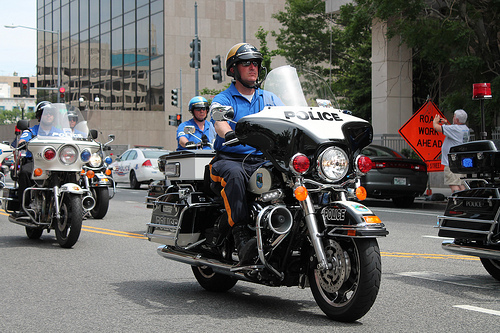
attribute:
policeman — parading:
[175, 95, 215, 150]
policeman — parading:
[15, 98, 64, 209]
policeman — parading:
[207, 40, 290, 255]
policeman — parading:
[67, 109, 77, 130]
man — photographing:
[431, 106, 472, 193]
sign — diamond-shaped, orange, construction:
[397, 95, 449, 169]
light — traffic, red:
[19, 76, 33, 97]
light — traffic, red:
[56, 84, 68, 102]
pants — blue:
[209, 155, 262, 232]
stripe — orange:
[208, 161, 233, 226]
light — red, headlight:
[44, 148, 58, 159]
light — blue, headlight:
[79, 149, 93, 163]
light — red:
[469, 80, 493, 99]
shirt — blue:
[210, 84, 284, 154]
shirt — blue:
[20, 124, 66, 157]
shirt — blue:
[177, 119, 216, 143]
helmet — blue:
[187, 94, 210, 110]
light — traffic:
[170, 87, 180, 108]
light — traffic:
[208, 53, 225, 84]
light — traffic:
[188, 38, 204, 70]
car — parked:
[353, 144, 428, 207]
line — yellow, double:
[1, 207, 481, 265]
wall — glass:
[33, 2, 167, 146]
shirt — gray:
[440, 121, 470, 165]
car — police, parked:
[110, 145, 173, 189]